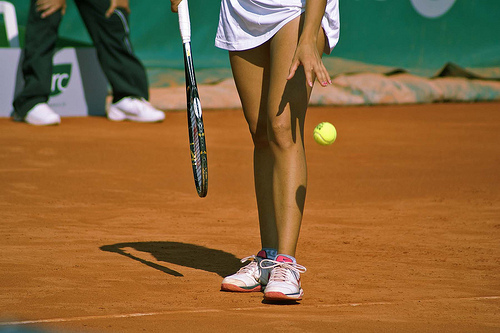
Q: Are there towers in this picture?
A: No, there are no towers.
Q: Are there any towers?
A: No, there are no towers.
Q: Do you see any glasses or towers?
A: No, there are no towers or glasses.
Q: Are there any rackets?
A: Yes, there is a racket.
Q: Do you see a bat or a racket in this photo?
A: Yes, there is a racket.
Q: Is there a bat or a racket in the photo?
A: Yes, there is a racket.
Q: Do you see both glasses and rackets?
A: No, there is a racket but no glasses.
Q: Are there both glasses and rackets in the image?
A: No, there is a racket but no glasses.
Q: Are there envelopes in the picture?
A: No, there are no envelopes.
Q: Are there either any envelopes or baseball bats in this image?
A: No, there are no envelopes or baseball bats.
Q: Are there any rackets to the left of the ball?
A: Yes, there is a racket to the left of the ball.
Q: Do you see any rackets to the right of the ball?
A: No, the racket is to the left of the ball.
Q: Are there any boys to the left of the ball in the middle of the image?
A: No, there is a racket to the left of the ball.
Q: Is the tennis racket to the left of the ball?
A: Yes, the tennis racket is to the left of the ball.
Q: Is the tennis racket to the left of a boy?
A: No, the tennis racket is to the left of the ball.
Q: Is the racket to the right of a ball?
A: No, the racket is to the left of a ball.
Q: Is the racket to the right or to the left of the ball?
A: The racket is to the left of the ball.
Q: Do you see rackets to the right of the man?
A: Yes, there is a racket to the right of the man.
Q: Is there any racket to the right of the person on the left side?
A: Yes, there is a racket to the right of the man.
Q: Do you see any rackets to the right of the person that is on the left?
A: Yes, there is a racket to the right of the man.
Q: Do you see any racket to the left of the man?
A: No, the racket is to the right of the man.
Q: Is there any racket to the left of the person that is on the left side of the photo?
A: No, the racket is to the right of the man.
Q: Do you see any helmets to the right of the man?
A: No, there is a racket to the right of the man.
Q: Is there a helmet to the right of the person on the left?
A: No, there is a racket to the right of the man.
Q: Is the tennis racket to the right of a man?
A: Yes, the tennis racket is to the right of a man.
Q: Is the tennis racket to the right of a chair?
A: No, the tennis racket is to the right of a man.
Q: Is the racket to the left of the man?
A: No, the racket is to the right of the man.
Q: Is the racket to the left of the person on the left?
A: No, the racket is to the right of the man.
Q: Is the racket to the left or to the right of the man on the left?
A: The racket is to the right of the man.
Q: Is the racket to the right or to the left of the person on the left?
A: The racket is to the right of the man.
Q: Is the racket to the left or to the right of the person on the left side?
A: The racket is to the right of the man.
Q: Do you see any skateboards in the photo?
A: No, there are no skateboards.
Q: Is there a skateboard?
A: No, there are no skateboards.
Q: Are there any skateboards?
A: No, there are no skateboards.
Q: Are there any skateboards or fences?
A: No, there are no skateboards or fences.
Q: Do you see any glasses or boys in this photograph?
A: No, there are no boys or glasses.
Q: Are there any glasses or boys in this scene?
A: No, there are no boys or glasses.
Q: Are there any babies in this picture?
A: No, there are no babies.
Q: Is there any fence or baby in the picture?
A: No, there are no babies or fences.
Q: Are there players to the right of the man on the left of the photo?
A: Yes, there is a player to the right of the man.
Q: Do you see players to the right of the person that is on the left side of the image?
A: Yes, there is a player to the right of the man.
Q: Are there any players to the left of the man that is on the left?
A: No, the player is to the right of the man.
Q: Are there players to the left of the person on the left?
A: No, the player is to the right of the man.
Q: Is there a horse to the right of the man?
A: No, there is a player to the right of the man.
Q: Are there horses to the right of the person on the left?
A: No, there is a player to the right of the man.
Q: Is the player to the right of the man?
A: Yes, the player is to the right of the man.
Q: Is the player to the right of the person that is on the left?
A: Yes, the player is to the right of the man.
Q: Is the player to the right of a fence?
A: No, the player is to the right of the man.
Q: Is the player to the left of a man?
A: No, the player is to the right of a man.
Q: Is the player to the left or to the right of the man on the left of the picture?
A: The player is to the right of the man.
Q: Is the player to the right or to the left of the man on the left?
A: The player is to the right of the man.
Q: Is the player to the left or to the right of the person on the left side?
A: The player is to the right of the man.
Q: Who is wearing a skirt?
A: The player is wearing a skirt.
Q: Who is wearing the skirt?
A: The player is wearing a skirt.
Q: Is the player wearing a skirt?
A: Yes, the player is wearing a skirt.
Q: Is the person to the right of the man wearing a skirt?
A: Yes, the player is wearing a skirt.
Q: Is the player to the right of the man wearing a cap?
A: No, the player is wearing a skirt.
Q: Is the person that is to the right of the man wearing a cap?
A: No, the player is wearing a skirt.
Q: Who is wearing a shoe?
A: The player is wearing a shoe.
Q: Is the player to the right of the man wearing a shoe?
A: Yes, the player is wearing a shoe.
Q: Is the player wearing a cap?
A: No, the player is wearing a shoe.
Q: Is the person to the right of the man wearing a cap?
A: No, the player is wearing a shoe.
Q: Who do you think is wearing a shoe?
A: The player is wearing a shoe.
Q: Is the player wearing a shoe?
A: Yes, the player is wearing a shoe.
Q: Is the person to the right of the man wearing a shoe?
A: Yes, the player is wearing a shoe.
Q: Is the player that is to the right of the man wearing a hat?
A: No, the player is wearing a shoe.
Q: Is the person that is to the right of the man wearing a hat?
A: No, the player is wearing a shoe.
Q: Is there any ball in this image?
A: Yes, there is a ball.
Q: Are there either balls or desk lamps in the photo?
A: Yes, there is a ball.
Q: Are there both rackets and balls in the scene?
A: Yes, there are both a ball and a racket.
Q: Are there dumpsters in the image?
A: No, there are no dumpsters.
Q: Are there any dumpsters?
A: No, there are no dumpsters.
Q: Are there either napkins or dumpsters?
A: No, there are no dumpsters or napkins.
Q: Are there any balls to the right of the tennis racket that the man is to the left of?
A: Yes, there is a ball to the right of the racket.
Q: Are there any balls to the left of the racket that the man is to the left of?
A: No, the ball is to the right of the tennis racket.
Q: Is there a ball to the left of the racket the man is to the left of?
A: No, the ball is to the right of the tennis racket.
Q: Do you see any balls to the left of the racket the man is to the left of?
A: No, the ball is to the right of the tennis racket.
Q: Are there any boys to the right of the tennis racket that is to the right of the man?
A: No, there is a ball to the right of the tennis racket.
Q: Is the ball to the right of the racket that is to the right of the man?
A: Yes, the ball is to the right of the racket.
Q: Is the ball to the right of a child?
A: No, the ball is to the right of the racket.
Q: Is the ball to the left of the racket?
A: No, the ball is to the right of the racket.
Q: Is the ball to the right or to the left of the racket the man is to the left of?
A: The ball is to the right of the tennis racket.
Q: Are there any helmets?
A: No, there are no helmets.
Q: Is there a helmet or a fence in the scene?
A: No, there are no helmets or fences.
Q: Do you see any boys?
A: No, there are no boys.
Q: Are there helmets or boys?
A: No, there are no boys or helmets.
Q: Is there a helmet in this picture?
A: No, there are no helmets.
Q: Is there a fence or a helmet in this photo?
A: No, there are no helmets or fences.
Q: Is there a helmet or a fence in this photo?
A: No, there are no helmets or fences.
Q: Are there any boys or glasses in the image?
A: No, there are no boys or glasses.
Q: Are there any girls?
A: No, there are no girls.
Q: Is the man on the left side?
A: Yes, the man is on the left of the image.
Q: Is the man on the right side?
A: No, the man is on the left of the image.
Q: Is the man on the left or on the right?
A: The man is on the left of the image.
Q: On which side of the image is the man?
A: The man is on the left of the image.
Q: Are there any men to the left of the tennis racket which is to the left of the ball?
A: Yes, there is a man to the left of the tennis racket.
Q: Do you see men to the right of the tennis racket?
A: No, the man is to the left of the tennis racket.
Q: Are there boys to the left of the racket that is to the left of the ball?
A: No, there is a man to the left of the racket.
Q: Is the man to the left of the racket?
A: Yes, the man is to the left of the racket.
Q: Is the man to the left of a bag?
A: No, the man is to the left of the racket.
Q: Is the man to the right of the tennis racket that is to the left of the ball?
A: No, the man is to the left of the racket.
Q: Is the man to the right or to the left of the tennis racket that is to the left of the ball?
A: The man is to the left of the tennis racket.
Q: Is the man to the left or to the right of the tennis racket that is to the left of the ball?
A: The man is to the left of the tennis racket.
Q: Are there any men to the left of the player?
A: Yes, there is a man to the left of the player.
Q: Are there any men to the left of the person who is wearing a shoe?
A: Yes, there is a man to the left of the player.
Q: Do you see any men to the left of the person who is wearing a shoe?
A: Yes, there is a man to the left of the player.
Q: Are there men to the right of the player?
A: No, the man is to the left of the player.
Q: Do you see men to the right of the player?
A: No, the man is to the left of the player.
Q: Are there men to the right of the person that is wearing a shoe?
A: No, the man is to the left of the player.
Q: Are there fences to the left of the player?
A: No, there is a man to the left of the player.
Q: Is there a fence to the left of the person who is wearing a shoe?
A: No, there is a man to the left of the player.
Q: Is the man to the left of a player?
A: Yes, the man is to the left of a player.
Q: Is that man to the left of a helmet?
A: No, the man is to the left of a player.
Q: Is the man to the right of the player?
A: No, the man is to the left of the player.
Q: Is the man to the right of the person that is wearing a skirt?
A: No, the man is to the left of the player.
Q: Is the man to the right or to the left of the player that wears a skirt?
A: The man is to the left of the player.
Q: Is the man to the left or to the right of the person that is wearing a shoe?
A: The man is to the left of the player.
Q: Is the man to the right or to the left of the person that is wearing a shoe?
A: The man is to the left of the player.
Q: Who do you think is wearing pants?
A: The man is wearing pants.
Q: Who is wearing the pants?
A: The man is wearing pants.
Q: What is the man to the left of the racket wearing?
A: The man is wearing trousers.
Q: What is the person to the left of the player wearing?
A: The man is wearing trousers.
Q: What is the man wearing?
A: The man is wearing trousers.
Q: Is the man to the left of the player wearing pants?
A: Yes, the man is wearing pants.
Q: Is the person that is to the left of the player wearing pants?
A: Yes, the man is wearing pants.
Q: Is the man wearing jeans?
A: No, the man is wearing pants.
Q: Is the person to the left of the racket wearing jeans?
A: No, the man is wearing pants.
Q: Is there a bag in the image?
A: No, there are no bags.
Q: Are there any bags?
A: No, there are no bags.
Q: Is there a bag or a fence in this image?
A: No, there are no bags or fences.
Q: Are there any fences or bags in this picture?
A: No, there are no bags or fences.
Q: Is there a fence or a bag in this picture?
A: No, there are no bags or fences.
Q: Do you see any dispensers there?
A: No, there are no dispensers.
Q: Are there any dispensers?
A: No, there are no dispensers.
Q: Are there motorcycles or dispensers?
A: No, there are no dispensers or motorcycles.